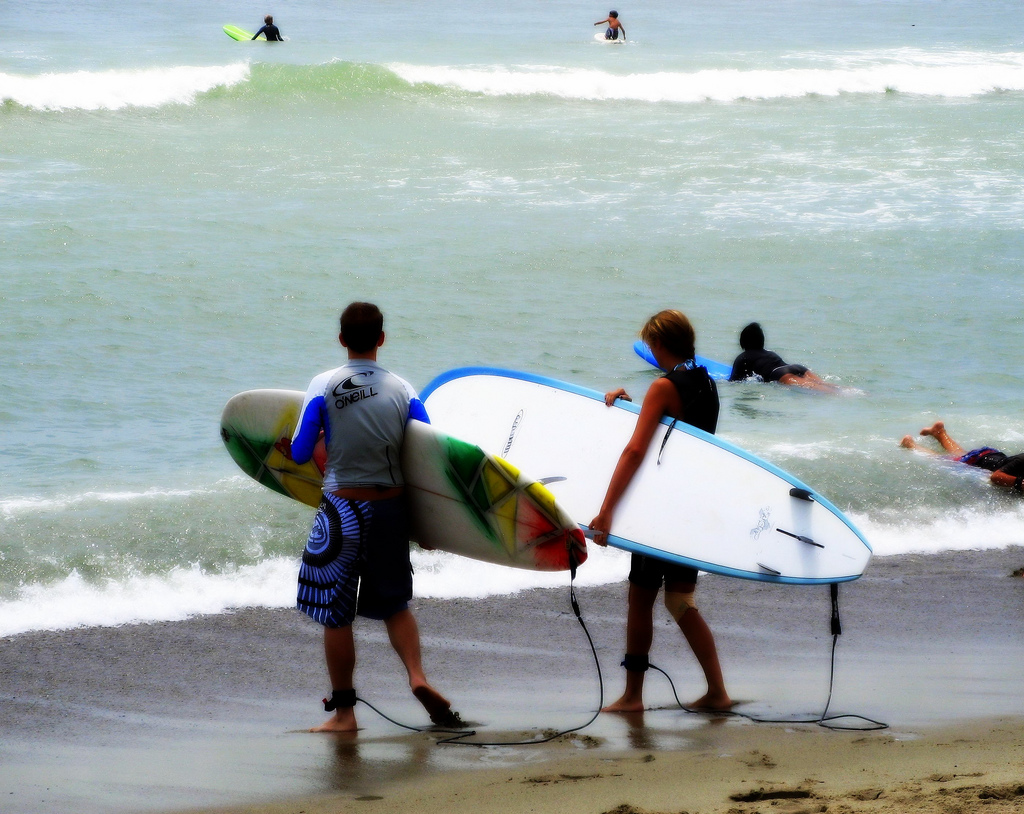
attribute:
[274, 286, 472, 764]
boy — young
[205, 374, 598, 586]
surfboard — green, white, yellow, red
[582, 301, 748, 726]
surfer — black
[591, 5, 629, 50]
boy — young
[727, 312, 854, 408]
surfer — young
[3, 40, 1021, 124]
waves — breaking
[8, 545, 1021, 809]
sand — wet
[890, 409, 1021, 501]
child — young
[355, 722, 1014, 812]
sand — dry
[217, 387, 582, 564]
surfboard — with, green, red, yellow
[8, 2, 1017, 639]
wavy — blue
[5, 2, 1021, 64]
water — bluer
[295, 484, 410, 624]
shorts — blue, black, swimming short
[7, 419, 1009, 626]
wave — white, grey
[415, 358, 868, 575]
surfboard — white, blue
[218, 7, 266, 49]
surfboard — green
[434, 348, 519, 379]
trim — blue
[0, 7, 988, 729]
water — wavy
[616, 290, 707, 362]
hair — black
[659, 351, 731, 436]
shirt — black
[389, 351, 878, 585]
surfboard — blue, white